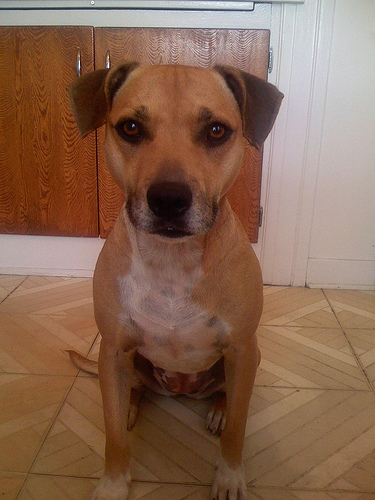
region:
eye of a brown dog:
[200, 118, 232, 149]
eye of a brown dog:
[119, 113, 145, 143]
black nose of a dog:
[147, 182, 192, 218]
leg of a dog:
[87, 300, 136, 499]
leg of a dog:
[203, 302, 263, 498]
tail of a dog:
[57, 344, 103, 378]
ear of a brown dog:
[213, 59, 289, 154]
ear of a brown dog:
[63, 56, 140, 137]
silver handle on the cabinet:
[73, 40, 85, 80]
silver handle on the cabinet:
[102, 46, 113, 70]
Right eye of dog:
[114, 112, 150, 150]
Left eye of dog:
[191, 110, 234, 150]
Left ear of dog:
[208, 55, 288, 158]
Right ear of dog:
[63, 58, 142, 146]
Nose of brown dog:
[140, 178, 196, 222]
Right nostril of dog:
[147, 193, 169, 214]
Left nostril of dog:
[170, 192, 190, 213]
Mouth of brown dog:
[114, 188, 231, 255]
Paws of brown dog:
[80, 400, 264, 498]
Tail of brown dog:
[60, 342, 104, 381]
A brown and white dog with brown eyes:
[45, 43, 298, 497]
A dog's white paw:
[203, 451, 254, 499]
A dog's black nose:
[140, 176, 201, 221]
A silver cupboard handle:
[59, 38, 94, 81]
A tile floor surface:
[268, 299, 370, 487]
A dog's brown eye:
[191, 107, 240, 154]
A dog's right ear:
[70, 58, 138, 138]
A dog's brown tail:
[59, 334, 108, 389]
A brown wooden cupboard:
[4, 16, 103, 242]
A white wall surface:
[331, 17, 373, 258]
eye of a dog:
[117, 117, 140, 140]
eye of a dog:
[208, 122, 227, 137]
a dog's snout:
[124, 160, 219, 238]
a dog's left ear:
[219, 67, 281, 151]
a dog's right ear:
[69, 59, 127, 137]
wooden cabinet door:
[0, 26, 97, 238]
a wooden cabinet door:
[93, 26, 255, 244]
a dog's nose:
[147, 183, 190, 216]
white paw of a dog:
[212, 457, 246, 498]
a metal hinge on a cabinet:
[265, 48, 273, 72]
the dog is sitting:
[41, 30, 305, 488]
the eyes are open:
[66, 85, 242, 164]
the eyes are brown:
[94, 98, 243, 158]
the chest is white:
[111, 233, 227, 364]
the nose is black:
[133, 174, 204, 224]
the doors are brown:
[1, 134, 112, 237]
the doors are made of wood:
[5, 148, 106, 229]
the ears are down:
[46, 38, 306, 173]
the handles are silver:
[47, 41, 125, 83]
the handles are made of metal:
[57, 39, 121, 87]